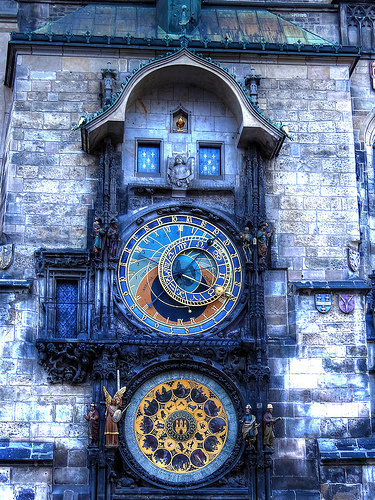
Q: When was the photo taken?
A: During the day.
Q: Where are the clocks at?
A: On the wall.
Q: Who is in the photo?
A: Nobody.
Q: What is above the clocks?
A: A statue.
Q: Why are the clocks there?
A: To decorate the place.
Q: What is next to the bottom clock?
A: More statues.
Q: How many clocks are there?
A: Two.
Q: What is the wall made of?
A: Blocks.